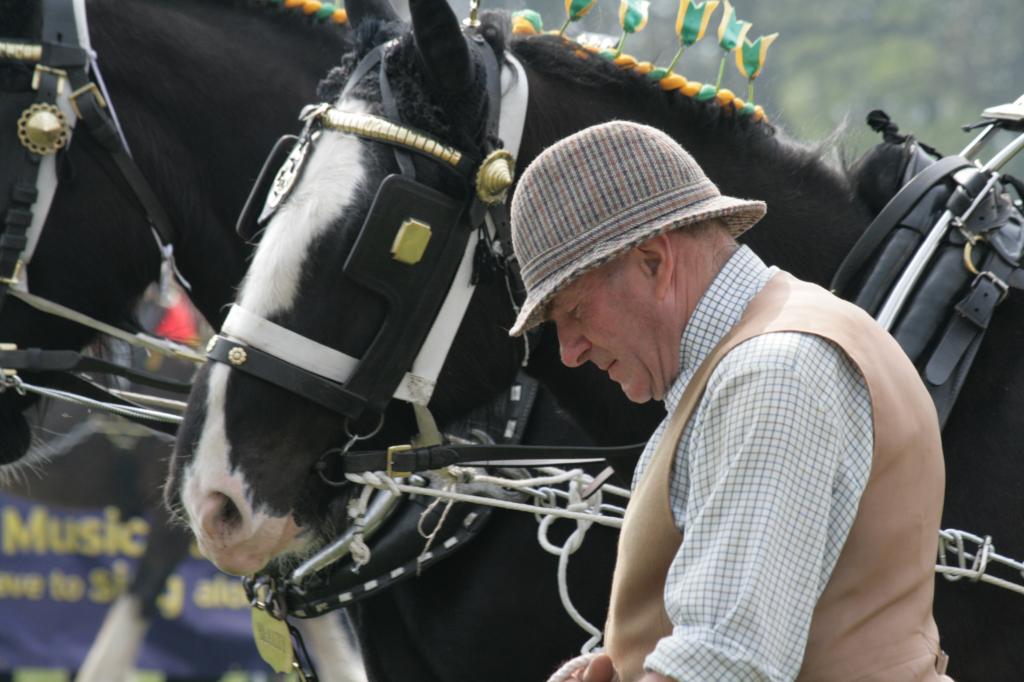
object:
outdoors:
[123, 103, 966, 624]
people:
[76, 450, 367, 682]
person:
[507, 119, 945, 536]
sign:
[0, 499, 151, 682]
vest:
[852, 390, 947, 650]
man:
[547, 217, 955, 682]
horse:
[235, 102, 463, 296]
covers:
[315, 232, 471, 487]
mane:
[575, 107, 706, 136]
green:
[829, 209, 857, 227]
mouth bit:
[265, 460, 319, 575]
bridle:
[241, 367, 540, 621]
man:
[507, 119, 951, 680]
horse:
[162, 0, 1022, 679]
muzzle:
[202, 490, 245, 540]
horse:
[0, 0, 351, 467]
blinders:
[340, 173, 461, 299]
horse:
[162, 0, 869, 674]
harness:
[205, 28, 530, 420]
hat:
[507, 119, 765, 337]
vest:
[603, 270, 954, 681]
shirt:
[630, 243, 876, 679]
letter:
[76, 517, 103, 557]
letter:
[106, 507, 152, 559]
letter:
[47, 518, 75, 555]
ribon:
[510, 9, 768, 129]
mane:
[509, 34, 778, 162]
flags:
[548, 0, 780, 128]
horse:
[2, 0, 624, 680]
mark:
[191, 99, 366, 476]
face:
[161, 61, 449, 577]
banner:
[2, 495, 276, 682]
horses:
[2, 0, 1024, 673]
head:
[548, 217, 742, 403]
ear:
[633, 233, 674, 298]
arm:
[638, 361, 832, 681]